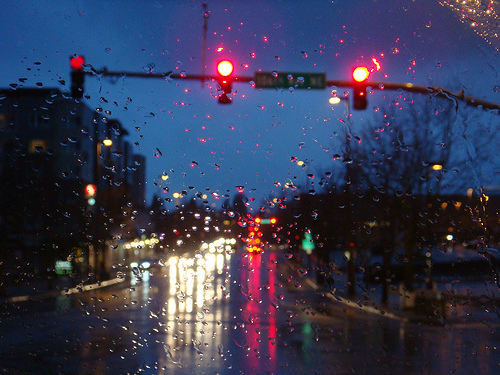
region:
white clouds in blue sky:
[15, 17, 56, 50]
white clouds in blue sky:
[104, 25, 150, 47]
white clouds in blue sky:
[266, 33, 305, 58]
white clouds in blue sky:
[399, 40, 457, 52]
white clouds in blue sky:
[399, 30, 446, 77]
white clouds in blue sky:
[240, 122, 284, 163]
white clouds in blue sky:
[148, 106, 209, 171]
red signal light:
[191, 48, 243, 127]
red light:
[337, 59, 376, 100]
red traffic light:
[70, 51, 112, 111]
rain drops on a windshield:
[61, 11, 431, 373]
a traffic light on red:
[349, 68, 370, 110]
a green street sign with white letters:
[248, 69, 329, 91]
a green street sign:
[300, 233, 314, 275]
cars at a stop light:
[238, 215, 261, 255]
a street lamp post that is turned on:
[94, 133, 116, 279]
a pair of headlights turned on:
[129, 262, 148, 269]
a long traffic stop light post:
[66, 51, 498, 119]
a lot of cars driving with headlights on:
[163, 233, 234, 280]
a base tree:
[348, 83, 478, 323]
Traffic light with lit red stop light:
[213, 58, 237, 103]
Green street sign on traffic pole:
[253, 70, 326, 90]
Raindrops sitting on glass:
[3, 5, 498, 370]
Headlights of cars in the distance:
[165, 233, 235, 321]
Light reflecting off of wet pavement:
[239, 250, 279, 363]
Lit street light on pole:
[326, 92, 350, 111]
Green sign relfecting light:
[301, 233, 314, 250]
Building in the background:
[2, 87, 146, 302]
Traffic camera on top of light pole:
[199, 0, 211, 75]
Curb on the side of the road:
[283, 249, 417, 322]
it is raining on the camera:
[16, 25, 410, 362]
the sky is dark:
[155, 120, 317, 190]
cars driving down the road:
[99, 203, 251, 313]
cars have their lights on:
[130, 213, 220, 320]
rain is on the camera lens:
[127, 136, 277, 243]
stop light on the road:
[236, 205, 291, 266]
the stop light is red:
[237, 200, 287, 242]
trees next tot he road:
[303, 100, 453, 312]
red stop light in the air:
[181, 13, 313, 135]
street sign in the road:
[254, 47, 385, 122]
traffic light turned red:
[351, 59, 369, 113]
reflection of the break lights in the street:
[237, 251, 282, 363]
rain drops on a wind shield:
[1, 1, 499, 371]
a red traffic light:
[208, 52, 238, 105]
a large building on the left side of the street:
[2, 85, 154, 270]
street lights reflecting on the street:
[155, 228, 232, 356]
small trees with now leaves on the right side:
[335, 78, 486, 302]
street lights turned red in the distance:
[248, 214, 289, 231]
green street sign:
[243, 70, 331, 95]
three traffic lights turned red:
[55, 39, 372, 124]